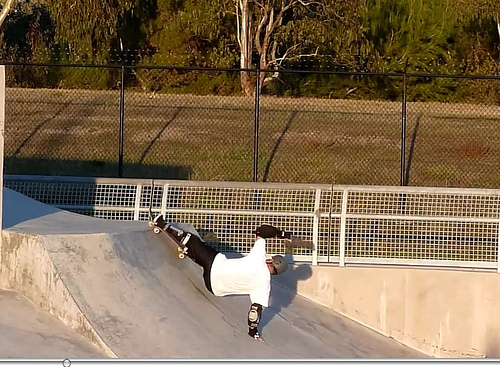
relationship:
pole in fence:
[337, 181, 349, 267] [4, 172, 497, 268]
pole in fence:
[306, 171, 321, 263] [4, 172, 497, 268]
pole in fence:
[336, 189, 350, 268] [4, 172, 497, 268]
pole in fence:
[310, 187, 325, 267] [4, 172, 497, 268]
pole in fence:
[113, 60, 126, 177] [4, 57, 484, 190]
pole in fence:
[248, 64, 260, 176] [4, 57, 484, 190]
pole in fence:
[395, 66, 411, 183] [4, 57, 484, 190]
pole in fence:
[339, 188, 348, 267] [15, 169, 498, 275]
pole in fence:
[339, 188, 348, 267] [4, 172, 497, 268]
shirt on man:
[208, 236, 273, 318] [153, 196, 325, 337]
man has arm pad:
[139, 199, 301, 345] [243, 304, 265, 330]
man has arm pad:
[139, 199, 301, 345] [254, 220, 287, 245]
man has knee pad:
[152, 214, 293, 343] [174, 224, 202, 261]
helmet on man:
[264, 251, 290, 280] [153, 200, 283, 334]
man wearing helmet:
[152, 214, 293, 343] [270, 254, 287, 273]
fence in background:
[365, 191, 400, 259] [12, 16, 480, 254]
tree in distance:
[353, 1, 470, 96] [14, 10, 484, 125]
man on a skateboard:
[152, 214, 293, 343] [147, 204, 187, 259]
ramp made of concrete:
[40, 218, 430, 365] [6, 186, 401, 365]